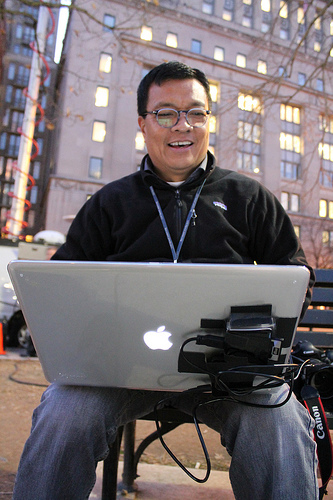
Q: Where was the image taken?
A: It was taken at the park.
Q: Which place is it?
A: It is a park.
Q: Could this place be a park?
A: Yes, it is a park.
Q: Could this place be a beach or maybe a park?
A: It is a park.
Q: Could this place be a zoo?
A: No, it is a park.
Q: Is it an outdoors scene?
A: Yes, it is outdoors.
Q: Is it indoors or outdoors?
A: It is outdoors.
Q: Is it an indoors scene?
A: No, it is outdoors.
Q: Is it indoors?
A: No, it is outdoors.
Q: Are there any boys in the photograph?
A: No, there are no boys.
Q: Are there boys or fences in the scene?
A: No, there are no boys or fences.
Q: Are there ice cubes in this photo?
A: No, there are no ice cubes.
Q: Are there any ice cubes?
A: No, there are no ice cubes.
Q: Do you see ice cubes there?
A: No, there are no ice cubes.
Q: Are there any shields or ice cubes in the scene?
A: No, there are no ice cubes or shields.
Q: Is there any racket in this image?
A: No, there are no rackets.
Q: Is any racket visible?
A: No, there are no rackets.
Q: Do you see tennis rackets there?
A: No, there are no tennis rackets.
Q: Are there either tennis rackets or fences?
A: No, there are no tennis rackets or fences.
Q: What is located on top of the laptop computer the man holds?
A: The logo is on top of the laptop computer.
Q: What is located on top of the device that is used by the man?
A: The logo is on top of the laptop computer.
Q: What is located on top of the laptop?
A: The logo is on top of the laptop computer.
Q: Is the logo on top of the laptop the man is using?
A: Yes, the logo is on top of the laptop.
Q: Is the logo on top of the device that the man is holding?
A: Yes, the logo is on top of the laptop.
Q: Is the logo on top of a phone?
A: No, the logo is on top of the laptop.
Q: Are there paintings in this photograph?
A: No, there are no paintings.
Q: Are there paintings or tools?
A: No, there are no paintings or tools.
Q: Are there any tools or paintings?
A: No, there are no paintings or tools.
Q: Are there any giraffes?
A: No, there are no giraffes.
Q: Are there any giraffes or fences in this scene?
A: No, there are no giraffes or fences.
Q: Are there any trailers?
A: No, there are no trailers.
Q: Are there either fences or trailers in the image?
A: No, there are no trailers or fences.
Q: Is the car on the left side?
A: Yes, the car is on the left of the image.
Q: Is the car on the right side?
A: No, the car is on the left of the image.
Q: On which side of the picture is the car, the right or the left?
A: The car is on the left of the image.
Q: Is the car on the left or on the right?
A: The car is on the left of the image.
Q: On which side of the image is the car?
A: The car is on the left of the image.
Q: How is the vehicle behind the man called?
A: The vehicle is a car.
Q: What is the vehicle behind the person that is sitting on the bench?
A: The vehicle is a car.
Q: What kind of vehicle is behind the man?
A: The vehicle is a car.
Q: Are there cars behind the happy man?
A: Yes, there is a car behind the man.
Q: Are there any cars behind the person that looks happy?
A: Yes, there is a car behind the man.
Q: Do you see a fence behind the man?
A: No, there is a car behind the man.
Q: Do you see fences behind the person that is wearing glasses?
A: No, there is a car behind the man.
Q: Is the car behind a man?
A: Yes, the car is behind a man.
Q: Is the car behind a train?
A: No, the car is behind a man.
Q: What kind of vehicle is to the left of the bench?
A: The vehicle is a car.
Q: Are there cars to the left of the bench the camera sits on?
A: Yes, there is a car to the left of the bench.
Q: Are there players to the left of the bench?
A: No, there is a car to the left of the bench.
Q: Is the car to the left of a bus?
A: No, the car is to the left of the bench.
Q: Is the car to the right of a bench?
A: No, the car is to the left of a bench.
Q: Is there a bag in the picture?
A: No, there are no bags.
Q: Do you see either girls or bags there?
A: No, there are no bags or girls.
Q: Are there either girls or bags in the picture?
A: No, there are no bags or girls.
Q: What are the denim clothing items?
A: The clothing items are jeans.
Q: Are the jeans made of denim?
A: Yes, the jeans are made of denim.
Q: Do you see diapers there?
A: No, there are no diapers.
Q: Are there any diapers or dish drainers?
A: No, there are no diapers or dish drainers.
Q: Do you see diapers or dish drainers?
A: No, there are no diapers or dish drainers.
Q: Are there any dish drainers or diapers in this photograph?
A: No, there are no diapers or dish drainers.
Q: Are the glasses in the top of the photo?
A: Yes, the glasses are in the top of the image.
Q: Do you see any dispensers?
A: No, there are no dispensers.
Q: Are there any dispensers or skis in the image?
A: No, there are no dispensers or skis.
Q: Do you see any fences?
A: No, there are no fences.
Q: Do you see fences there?
A: No, there are no fences.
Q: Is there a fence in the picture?
A: No, there are no fences.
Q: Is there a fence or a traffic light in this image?
A: No, there are no fences or traffic lights.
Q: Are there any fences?
A: No, there are no fences.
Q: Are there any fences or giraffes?
A: No, there are no fences or giraffes.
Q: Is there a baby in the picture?
A: No, there are no babies.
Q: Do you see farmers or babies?
A: No, there are no babies or farmers.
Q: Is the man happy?
A: Yes, the man is happy.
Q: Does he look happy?
A: Yes, the man is happy.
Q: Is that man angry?
A: No, the man is happy.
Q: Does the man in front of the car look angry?
A: No, the man is happy.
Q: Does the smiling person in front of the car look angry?
A: No, the man is happy.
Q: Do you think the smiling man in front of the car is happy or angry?
A: The man is happy.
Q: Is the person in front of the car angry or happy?
A: The man is happy.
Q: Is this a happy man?
A: Yes, this is a happy man.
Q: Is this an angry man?
A: No, this is a happy man.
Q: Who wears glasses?
A: The man wears glasses.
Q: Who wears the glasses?
A: The man wears glasses.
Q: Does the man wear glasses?
A: Yes, the man wears glasses.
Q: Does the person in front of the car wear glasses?
A: Yes, the man wears glasses.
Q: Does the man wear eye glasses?
A: No, the man wears glasses.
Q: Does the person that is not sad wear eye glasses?
A: No, the man wears glasses.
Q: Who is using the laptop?
A: The man is using the laptop.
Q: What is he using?
A: The man is using a laptop.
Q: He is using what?
A: The man is using a laptop.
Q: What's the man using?
A: The man is using a laptop.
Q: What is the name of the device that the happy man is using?
A: The device is a laptop.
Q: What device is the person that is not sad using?
A: The man is using a laptop.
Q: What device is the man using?
A: The man is using a laptop.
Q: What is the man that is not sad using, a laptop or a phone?
A: The man is using a laptop.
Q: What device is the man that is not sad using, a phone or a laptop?
A: The man is using a laptop.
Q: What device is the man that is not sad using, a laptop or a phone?
A: The man is using a laptop.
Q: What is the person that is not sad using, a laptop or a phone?
A: The man is using a laptop.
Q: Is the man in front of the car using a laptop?
A: Yes, the man is using a laptop.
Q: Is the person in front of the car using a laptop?
A: Yes, the man is using a laptop.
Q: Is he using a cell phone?
A: No, the man is using a laptop.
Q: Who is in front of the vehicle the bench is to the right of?
A: The man is in front of the car.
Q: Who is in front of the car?
A: The man is in front of the car.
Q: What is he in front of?
A: The man is in front of the car.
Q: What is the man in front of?
A: The man is in front of the car.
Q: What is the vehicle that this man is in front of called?
A: The vehicle is a car.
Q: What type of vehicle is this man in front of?
A: The man is in front of the car.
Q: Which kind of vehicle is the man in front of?
A: The man is in front of the car.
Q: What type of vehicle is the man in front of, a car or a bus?
A: The man is in front of a car.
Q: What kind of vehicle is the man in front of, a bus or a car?
A: The man is in front of a car.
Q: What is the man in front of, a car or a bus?
A: The man is in front of a car.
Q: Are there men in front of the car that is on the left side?
A: Yes, there is a man in front of the car.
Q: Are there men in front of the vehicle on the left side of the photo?
A: Yes, there is a man in front of the car.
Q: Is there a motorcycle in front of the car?
A: No, there is a man in front of the car.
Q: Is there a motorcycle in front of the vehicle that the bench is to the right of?
A: No, there is a man in front of the car.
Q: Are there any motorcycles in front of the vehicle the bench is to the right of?
A: No, there is a man in front of the car.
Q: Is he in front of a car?
A: Yes, the man is in front of a car.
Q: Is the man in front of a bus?
A: No, the man is in front of a car.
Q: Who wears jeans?
A: The man wears jeans.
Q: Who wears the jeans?
A: The man wears jeans.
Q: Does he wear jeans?
A: Yes, the man wears jeans.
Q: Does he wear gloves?
A: No, the man wears jeans.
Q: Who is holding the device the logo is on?
A: The man is holding the laptop.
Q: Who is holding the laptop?
A: The man is holding the laptop.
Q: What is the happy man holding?
A: The man is holding the laptop.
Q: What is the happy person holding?
A: The man is holding the laptop.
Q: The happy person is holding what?
A: The man is holding the laptop.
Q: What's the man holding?
A: The man is holding the laptop.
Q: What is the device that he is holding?
A: The device is a laptop.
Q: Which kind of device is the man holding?
A: The man is holding the laptop.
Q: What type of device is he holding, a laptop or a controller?
A: The man is holding a laptop.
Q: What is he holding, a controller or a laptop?
A: The man is holding a laptop.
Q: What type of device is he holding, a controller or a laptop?
A: The man is holding a laptop.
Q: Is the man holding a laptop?
A: Yes, the man is holding a laptop.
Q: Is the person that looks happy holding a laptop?
A: Yes, the man is holding a laptop.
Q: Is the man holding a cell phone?
A: No, the man is holding a laptop.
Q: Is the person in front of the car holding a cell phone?
A: No, the man is holding a laptop.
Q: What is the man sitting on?
A: The man is sitting on the bench.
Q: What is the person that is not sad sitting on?
A: The man is sitting on the bench.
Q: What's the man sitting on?
A: The man is sitting on the bench.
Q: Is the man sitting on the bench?
A: Yes, the man is sitting on the bench.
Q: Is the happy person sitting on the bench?
A: Yes, the man is sitting on the bench.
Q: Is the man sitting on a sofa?
A: No, the man is sitting on the bench.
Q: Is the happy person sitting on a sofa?
A: No, the man is sitting on the bench.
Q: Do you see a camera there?
A: Yes, there is a camera.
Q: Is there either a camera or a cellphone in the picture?
A: Yes, there is a camera.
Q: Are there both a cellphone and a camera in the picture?
A: No, there is a camera but no cell phones.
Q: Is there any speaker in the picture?
A: No, there are no speakers.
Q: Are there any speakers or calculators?
A: No, there are no speakers or calculators.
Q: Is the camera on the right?
A: Yes, the camera is on the right of the image.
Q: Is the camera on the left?
A: No, the camera is on the right of the image.